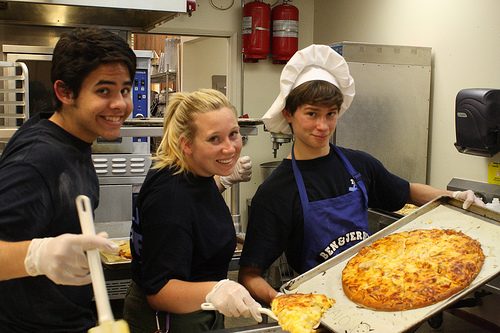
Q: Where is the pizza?
A: On the tray.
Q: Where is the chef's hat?
A: On the boy's head.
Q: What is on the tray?
A: The pizza.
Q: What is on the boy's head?
A: The chef's hat.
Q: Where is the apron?
A: On the boy.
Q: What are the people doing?
A: Cooking.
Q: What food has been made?
A: Pizza.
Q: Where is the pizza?
A: On the tray.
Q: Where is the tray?
A: In the chef's hands.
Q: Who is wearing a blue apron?
A: The chef.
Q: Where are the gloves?
A: On the people's hands.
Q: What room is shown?
A: Kitchen.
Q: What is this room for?
A: Cooking.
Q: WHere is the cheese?
A: On the pizza.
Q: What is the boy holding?
A: A pizza.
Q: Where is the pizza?
A: On a tray.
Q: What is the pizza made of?
A: Cheese.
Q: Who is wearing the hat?
A: The chef.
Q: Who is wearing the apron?
A: The chef.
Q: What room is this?
A: Kitchen.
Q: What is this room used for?
A: Cooking.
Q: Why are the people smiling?
A: For a picture.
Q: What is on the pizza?
A: Cheese.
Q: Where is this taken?
A: A restaurant.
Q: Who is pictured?
A: Two males one female.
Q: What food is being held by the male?
A: A pizza.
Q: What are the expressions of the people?
A: Happy and smiling.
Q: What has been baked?
A: Pizza.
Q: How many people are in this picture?
A: Three.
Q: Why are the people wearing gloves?
A: For sanitation.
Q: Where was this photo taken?
A: Kitchen.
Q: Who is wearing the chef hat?
A: The boy on the right.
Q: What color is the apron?
A: Blue.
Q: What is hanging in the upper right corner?
A: Fire Extinguishers.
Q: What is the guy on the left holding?
A: A spatula.